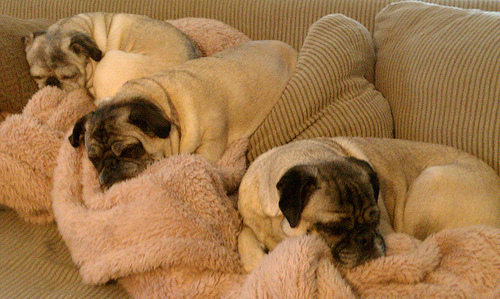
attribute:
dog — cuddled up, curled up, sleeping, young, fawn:
[66, 37, 300, 186]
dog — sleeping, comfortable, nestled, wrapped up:
[236, 137, 499, 277]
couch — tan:
[1, 1, 498, 296]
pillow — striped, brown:
[373, 1, 499, 177]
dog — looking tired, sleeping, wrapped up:
[24, 12, 205, 108]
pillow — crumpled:
[246, 14, 393, 163]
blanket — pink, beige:
[1, 15, 493, 290]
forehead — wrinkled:
[327, 171, 376, 218]